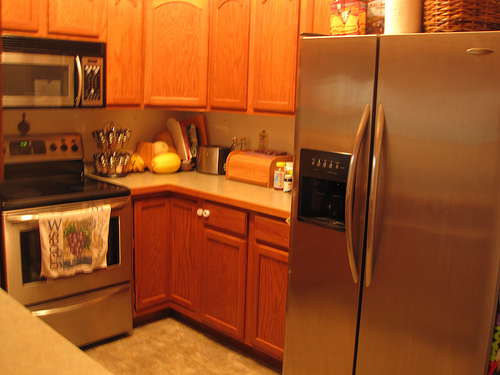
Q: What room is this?
A: Kitchen.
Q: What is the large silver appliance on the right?
A: A refrigerator.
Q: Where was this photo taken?
A: The kitchen.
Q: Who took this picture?
A: The homeowner.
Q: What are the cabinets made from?
A: Wood.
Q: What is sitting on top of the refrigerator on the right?
A: A wicker basket.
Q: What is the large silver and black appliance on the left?
A: A stove.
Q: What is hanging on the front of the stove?
A: A dish towel.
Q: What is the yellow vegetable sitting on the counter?
A: A squash.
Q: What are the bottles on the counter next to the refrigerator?
A: Vitamins and medicine.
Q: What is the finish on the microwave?
A: Stainless steel.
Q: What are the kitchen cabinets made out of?
A: Wood.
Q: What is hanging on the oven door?
A: A towel.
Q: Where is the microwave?
A: Over the stove.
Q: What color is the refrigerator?
A: Silver.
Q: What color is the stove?
A: Black and silver.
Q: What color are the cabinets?
A: Brown.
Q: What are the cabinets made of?
A: Wood.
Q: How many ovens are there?
A: One.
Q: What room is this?
A: Kitchen.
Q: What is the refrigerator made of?
A: Metal.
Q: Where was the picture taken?
A: In a kitchen.